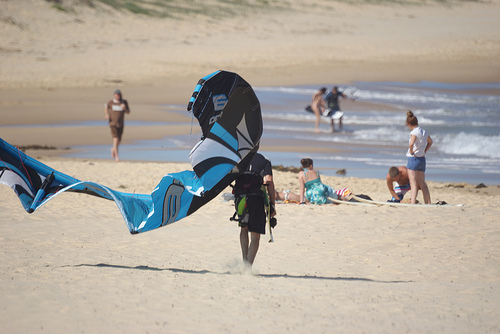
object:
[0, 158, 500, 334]
shore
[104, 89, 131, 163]
man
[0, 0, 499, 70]
dune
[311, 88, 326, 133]
woman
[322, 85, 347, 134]
man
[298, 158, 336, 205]
woman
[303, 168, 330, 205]
swimsuit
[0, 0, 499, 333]
beach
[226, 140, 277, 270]
man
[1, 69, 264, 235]
kite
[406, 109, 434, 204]
woman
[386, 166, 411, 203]
man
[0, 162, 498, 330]
sand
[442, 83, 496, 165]
water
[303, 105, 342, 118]
surfboard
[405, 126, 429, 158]
shirt